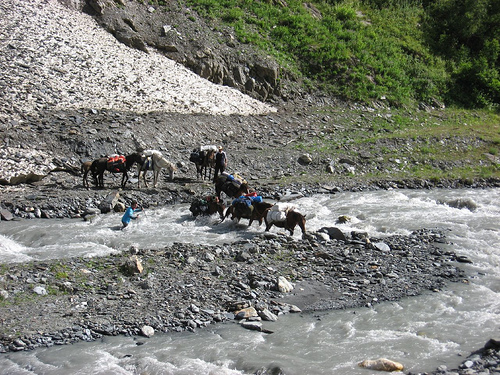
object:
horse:
[138, 145, 175, 184]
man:
[119, 197, 142, 229]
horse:
[79, 151, 143, 194]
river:
[2, 189, 499, 295]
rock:
[85, 206, 99, 214]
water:
[45, 221, 108, 257]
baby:
[199, 143, 217, 152]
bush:
[382, 80, 416, 108]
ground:
[257, 113, 434, 176]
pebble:
[370, 131, 384, 140]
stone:
[223, 129, 236, 137]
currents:
[1, 216, 91, 256]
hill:
[105, 8, 347, 104]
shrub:
[343, 74, 368, 97]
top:
[239, 188, 268, 207]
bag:
[107, 153, 126, 163]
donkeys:
[188, 143, 213, 180]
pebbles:
[32, 205, 44, 219]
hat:
[130, 200, 138, 205]